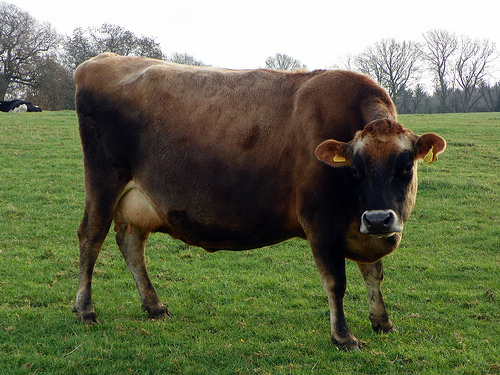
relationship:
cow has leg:
[71, 50, 448, 353] [359, 260, 394, 331]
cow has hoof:
[71, 50, 448, 353] [140, 302, 170, 319]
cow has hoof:
[71, 50, 448, 353] [333, 334, 368, 352]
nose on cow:
[359, 209, 402, 229] [71, 50, 448, 353]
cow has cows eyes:
[71, 50, 448, 353] [400, 163, 420, 175]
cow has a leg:
[71, 50, 448, 353] [73, 162, 134, 320]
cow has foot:
[71, 50, 448, 353] [327, 292, 362, 350]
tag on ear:
[419, 145, 433, 163] [415, 129, 448, 169]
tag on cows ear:
[419, 145, 433, 163] [415, 130, 448, 165]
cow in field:
[61, 40, 459, 354] [10, 109, 493, 372]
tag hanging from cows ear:
[419, 148, 439, 167] [415, 119, 443, 174]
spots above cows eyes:
[345, 126, 408, 161] [338, 146, 412, 187]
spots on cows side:
[149, 101, 285, 180] [90, 80, 318, 209]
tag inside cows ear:
[419, 145, 433, 163] [308, 129, 347, 167]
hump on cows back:
[296, 70, 398, 120] [89, 65, 365, 145]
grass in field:
[412, 175, 495, 339] [408, 101, 497, 354]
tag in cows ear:
[315, 150, 364, 169] [296, 113, 362, 190]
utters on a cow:
[112, 201, 162, 247] [0, 51, 473, 261]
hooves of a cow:
[65, 302, 404, 351] [68, 33, 494, 356]